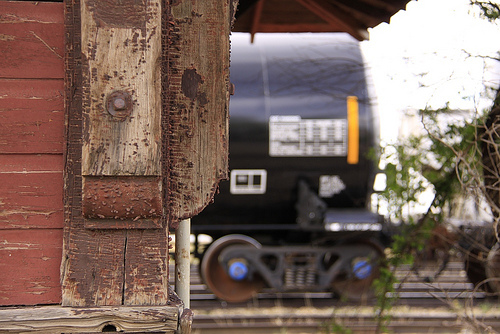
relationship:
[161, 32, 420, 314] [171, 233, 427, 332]
locomotive on rail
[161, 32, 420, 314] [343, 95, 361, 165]
locomotive has line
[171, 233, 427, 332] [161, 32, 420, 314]
rail under locomotive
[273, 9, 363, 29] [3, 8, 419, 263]
roof of building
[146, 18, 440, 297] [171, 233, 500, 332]
train on rail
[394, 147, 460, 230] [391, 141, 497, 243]
weed and shrub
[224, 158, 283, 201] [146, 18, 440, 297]
sign of train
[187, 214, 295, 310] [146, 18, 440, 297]
wheel of train